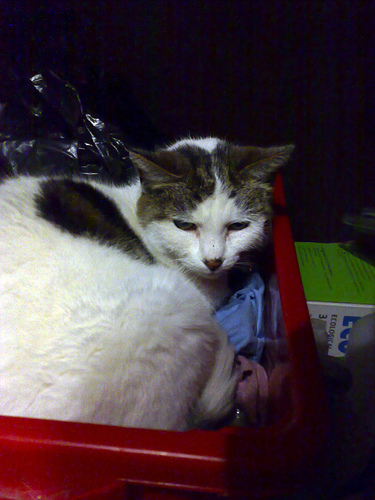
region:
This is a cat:
[18, 139, 292, 488]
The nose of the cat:
[205, 255, 221, 269]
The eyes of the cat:
[173, 217, 251, 231]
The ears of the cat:
[127, 145, 293, 183]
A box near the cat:
[294, 241, 373, 355]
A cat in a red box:
[2, 138, 295, 429]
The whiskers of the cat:
[230, 259, 249, 269]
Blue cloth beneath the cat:
[221, 273, 263, 350]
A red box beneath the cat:
[1, 160, 324, 498]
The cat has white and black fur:
[0, 137, 294, 429]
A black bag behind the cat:
[0, 74, 125, 181]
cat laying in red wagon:
[2, 60, 350, 497]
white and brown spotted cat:
[1, 117, 320, 452]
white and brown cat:
[2, 122, 319, 464]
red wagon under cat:
[6, 131, 366, 498]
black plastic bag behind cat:
[4, 72, 145, 204]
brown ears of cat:
[108, 132, 307, 207]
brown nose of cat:
[199, 253, 231, 270]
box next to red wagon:
[293, 224, 371, 360]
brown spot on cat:
[40, 168, 160, 277]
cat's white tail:
[199, 328, 256, 443]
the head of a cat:
[135, 130, 310, 270]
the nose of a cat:
[195, 242, 244, 307]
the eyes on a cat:
[157, 197, 283, 254]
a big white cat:
[45, 129, 361, 380]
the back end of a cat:
[8, 271, 266, 472]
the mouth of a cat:
[185, 242, 248, 296]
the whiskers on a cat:
[150, 229, 290, 296]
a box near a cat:
[275, 227, 369, 341]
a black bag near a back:
[40, 94, 220, 217]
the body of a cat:
[2, 128, 260, 406]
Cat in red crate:
[0, 134, 298, 430]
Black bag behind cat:
[0, 54, 136, 183]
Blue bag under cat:
[215, 271, 266, 361]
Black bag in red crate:
[0, 50, 139, 176]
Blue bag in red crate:
[205, 266, 265, 357]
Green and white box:
[294, 238, 374, 356]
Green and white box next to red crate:
[294, 240, 373, 362]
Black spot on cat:
[34, 175, 152, 263]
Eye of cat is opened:
[173, 215, 197, 232]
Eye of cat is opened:
[226, 218, 251, 233]